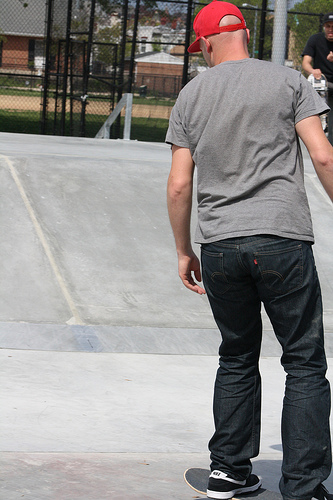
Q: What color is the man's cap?
A: Red.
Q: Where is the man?
A: Skate park.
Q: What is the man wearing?
A: Gray t shirt and jeans.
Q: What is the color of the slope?
A: Grey.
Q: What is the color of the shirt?
A: Grey.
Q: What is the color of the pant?
A: Blue.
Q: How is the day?
A: Sunny.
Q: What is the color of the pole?
A: Grey.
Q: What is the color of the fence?
A: Black.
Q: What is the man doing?
A: Skateboarding.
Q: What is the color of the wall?
A: Brown.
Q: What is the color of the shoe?
A: Black and white.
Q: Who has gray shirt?
A: The man.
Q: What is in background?
A: Black metal fence.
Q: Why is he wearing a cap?
A: To keep sun off his head.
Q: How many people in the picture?
A: Two.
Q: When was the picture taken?
A: Daytime.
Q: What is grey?
A: Shirt.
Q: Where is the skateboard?
A: On the ground.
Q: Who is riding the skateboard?
A: Man.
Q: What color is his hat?
A: Red.